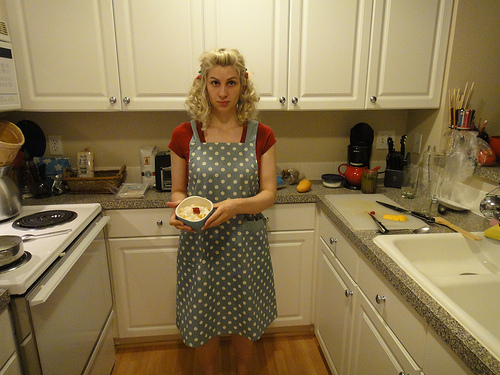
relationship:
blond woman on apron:
[165, 48, 277, 375] [171, 116, 273, 344]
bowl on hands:
[175, 195, 214, 229] [160, 196, 236, 232]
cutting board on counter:
[324, 192, 429, 229] [313, 180, 498, 360]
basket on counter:
[51, 158, 128, 200] [38, 174, 349, 209]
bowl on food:
[175, 195, 214, 228] [182, 204, 204, 220]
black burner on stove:
[12, 209, 77, 229] [10, 200, 134, 369]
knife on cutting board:
[400, 134, 407, 158] [315, 185, 432, 250]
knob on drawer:
[325, 235, 340, 248] [316, 211, 362, 279]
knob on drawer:
[325, 235, 340, 248] [355, 248, 426, 365]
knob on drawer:
[325, 235, 340, 248] [104, 209, 173, 235]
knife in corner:
[382, 134, 408, 169] [384, 110, 439, 202]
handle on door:
[27, 210, 112, 310] [20, 196, 132, 375]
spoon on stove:
[19, 230, 65, 238] [1, 199, 132, 375]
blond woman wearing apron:
[165, 48, 277, 375] [175, 119, 279, 348]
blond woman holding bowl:
[165, 48, 277, 375] [163, 192, 220, 231]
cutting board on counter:
[324, 192, 429, 229] [310, 167, 499, 372]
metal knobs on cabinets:
[279, 96, 374, 101] [6, 3, 448, 110]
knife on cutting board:
[359, 193, 449, 238] [318, 183, 435, 248]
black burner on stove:
[12, 201, 83, 233] [0, 184, 120, 374]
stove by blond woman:
[0, 203, 116, 375] [165, 48, 277, 375]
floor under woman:
[110, 323, 323, 373] [162, 32, 300, 374]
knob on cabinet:
[120, 94, 127, 106] [117, 2, 205, 116]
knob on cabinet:
[110, 96, 115, 110] [9, 1, 116, 115]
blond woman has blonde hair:
[165, 48, 277, 375] [190, 45, 259, 125]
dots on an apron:
[219, 252, 243, 287] [171, 116, 273, 344]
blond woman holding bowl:
[165, 48, 277, 375] [173, 194, 215, 230]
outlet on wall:
[47, 133, 62, 155] [403, 107, 438, 163]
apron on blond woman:
[175, 108, 276, 349] [165, 48, 277, 375]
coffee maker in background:
[325, 124, 374, 178] [0, 0, 500, 210]